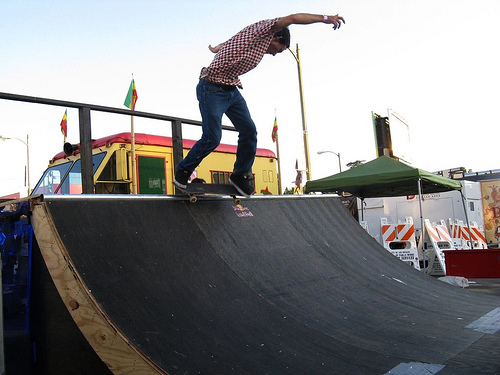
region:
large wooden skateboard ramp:
[37, 196, 490, 373]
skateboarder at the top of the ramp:
[170, 15, 340, 200]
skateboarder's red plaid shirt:
[197, 17, 267, 82]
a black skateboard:
[175, 177, 250, 197]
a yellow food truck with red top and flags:
[36, 75, 276, 190]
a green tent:
[305, 150, 465, 192]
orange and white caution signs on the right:
[385, 215, 485, 266]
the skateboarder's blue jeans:
[175, 80, 255, 171]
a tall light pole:
[290, 43, 312, 188]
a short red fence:
[442, 248, 498, 277]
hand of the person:
[281, 4, 348, 38]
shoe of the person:
[161, 170, 198, 182]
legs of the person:
[163, 119, 288, 175]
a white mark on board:
[379, 259, 425, 295]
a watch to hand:
[316, 8, 329, 28]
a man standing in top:
[176, 2, 356, 219]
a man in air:
[181, 5, 403, 210]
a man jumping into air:
[171, 3, 361, 206]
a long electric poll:
[283, 42, 330, 211]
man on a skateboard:
[178, 6, 358, 215]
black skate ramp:
[26, 164, 499, 374]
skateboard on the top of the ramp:
[169, 173, 249, 208]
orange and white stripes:
[383, 223, 418, 243]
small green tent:
[304, 157, 491, 283]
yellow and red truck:
[22, 128, 287, 205]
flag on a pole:
[265, 111, 287, 190]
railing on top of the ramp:
[2, 93, 264, 201]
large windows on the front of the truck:
[29, 156, 108, 193]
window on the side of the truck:
[132, 156, 176, 198]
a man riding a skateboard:
[172, 12, 345, 197]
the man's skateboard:
[171, 180, 254, 205]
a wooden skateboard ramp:
[0, 91, 498, 373]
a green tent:
[304, 154, 474, 274]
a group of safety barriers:
[359, 216, 487, 275]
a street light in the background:
[316, 149, 341, 172]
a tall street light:
[286, 41, 313, 194]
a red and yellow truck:
[27, 130, 277, 196]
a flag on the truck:
[122, 72, 139, 194]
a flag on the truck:
[270, 108, 282, 195]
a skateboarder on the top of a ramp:
[167, 0, 358, 215]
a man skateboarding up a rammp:
[170, 7, 352, 215]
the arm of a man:
[276, 10, 348, 30]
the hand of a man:
[205, 40, 220, 57]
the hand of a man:
[330, 11, 347, 32]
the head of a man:
[262, 22, 289, 62]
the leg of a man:
[230, 96, 258, 206]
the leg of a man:
[177, 96, 220, 186]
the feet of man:
[170, 161, 260, 196]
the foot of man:
[222, 170, 258, 200]